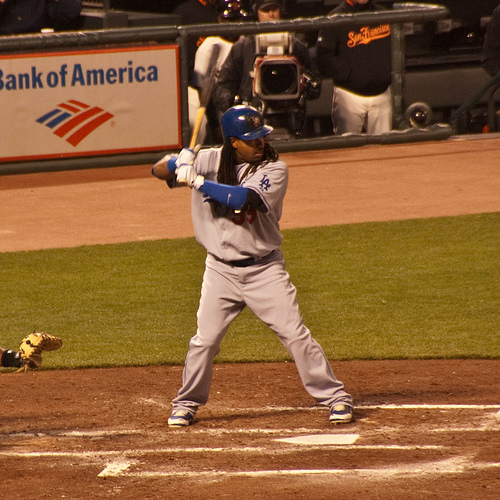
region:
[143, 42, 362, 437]
A hitter in the batter's box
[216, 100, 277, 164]
A player wearing a batting helmet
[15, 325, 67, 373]
A catcher's mitt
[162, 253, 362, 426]
Baggy baseball pants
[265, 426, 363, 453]
A home plate on a baseball diamond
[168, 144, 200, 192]
White baseball batter's gloves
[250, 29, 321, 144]
A television camera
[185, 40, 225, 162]
A baseball bat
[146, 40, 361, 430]
A baseball batter in a ready stance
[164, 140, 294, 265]
A baseball jersey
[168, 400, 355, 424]
cleats of player batting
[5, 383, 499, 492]
white chalk outline of batter's box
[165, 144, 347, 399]
gray and blue uniform of player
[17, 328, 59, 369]
tan glove of catcher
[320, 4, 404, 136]
player standing in dugout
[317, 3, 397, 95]
black and orange jacket of man in dugout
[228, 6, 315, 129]
camera and cameraman in dugout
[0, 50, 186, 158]
bank of america sign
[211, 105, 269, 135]
blue batting helmet of batter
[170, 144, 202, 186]
white batting gloves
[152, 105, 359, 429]
A baseball player preparing to bat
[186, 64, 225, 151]
A black baseball bat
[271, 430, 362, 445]
A baseball plate on the ground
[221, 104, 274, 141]
A blue baseball helmet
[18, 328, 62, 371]
A baseball glove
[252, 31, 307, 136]
A large camera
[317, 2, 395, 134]
A man in a black shirt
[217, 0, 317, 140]
A man in a black jacket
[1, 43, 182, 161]
A bank of america sign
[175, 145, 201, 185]
A pair of white gloves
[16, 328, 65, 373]
yellow catcher's mitt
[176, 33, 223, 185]
black and yellow wooden baseball bat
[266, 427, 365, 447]
flat white pentagonal home plate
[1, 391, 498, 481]
white chalk lining baseball field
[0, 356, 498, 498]
brown dirt batter's box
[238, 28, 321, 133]
large television camera aimed at baseball player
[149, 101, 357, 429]
baseball player waiting for a pitch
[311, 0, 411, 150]
baseball coach standing in dugout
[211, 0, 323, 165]
cameraman standing in dugout aiming camera at player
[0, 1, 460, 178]
dark brown railing around baseball field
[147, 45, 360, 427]
a man playing baseball on a baseball field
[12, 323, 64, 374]
a baseball mit on a hand on a baseball field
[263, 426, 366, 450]
a base on a baseball field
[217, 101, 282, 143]
a helmet on a man's head on a baseball field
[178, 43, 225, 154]
a baseball bat being swung on a baseball field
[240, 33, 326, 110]
a camera being held by a man on a baseball field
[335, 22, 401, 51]
words on a man's shirt on a baseball field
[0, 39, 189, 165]
a sign on a baseball field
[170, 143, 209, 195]
gloves on a man's hand holding a bat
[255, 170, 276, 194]
letters on a baseball shirt on a man